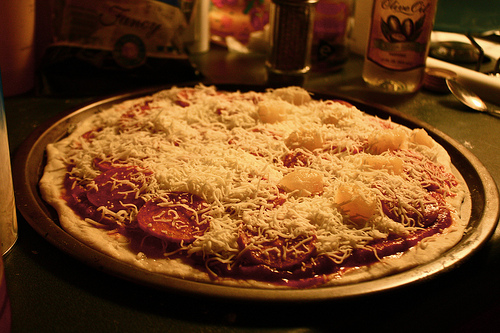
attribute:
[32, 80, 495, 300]
pizza — uncooked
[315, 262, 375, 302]
pan — metal, pizza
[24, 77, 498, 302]
pan — round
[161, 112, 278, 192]
cheese — mozzarella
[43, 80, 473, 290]
pizza — unfinished